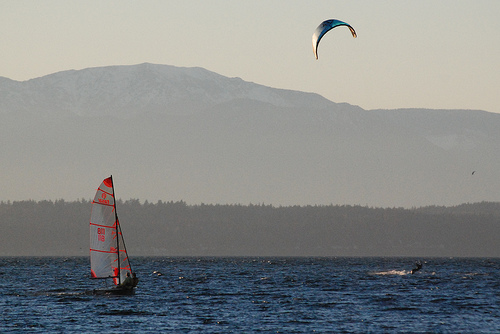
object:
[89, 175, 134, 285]
sail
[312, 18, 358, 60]
kite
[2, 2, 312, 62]
sky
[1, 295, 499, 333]
water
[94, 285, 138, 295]
boat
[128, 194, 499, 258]
trees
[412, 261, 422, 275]
man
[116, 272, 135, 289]
people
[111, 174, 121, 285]
mast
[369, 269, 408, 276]
wake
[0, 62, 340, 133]
mountains